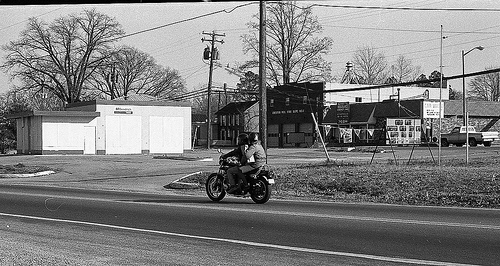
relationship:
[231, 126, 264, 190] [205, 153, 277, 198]
man riding motorcycle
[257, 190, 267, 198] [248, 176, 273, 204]
part belonging to wheel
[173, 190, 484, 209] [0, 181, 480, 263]
edge lining road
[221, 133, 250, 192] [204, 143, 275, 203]
man riding motorcycle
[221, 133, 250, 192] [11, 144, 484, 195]
man driving on road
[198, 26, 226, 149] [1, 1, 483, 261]
utility pole shown in picture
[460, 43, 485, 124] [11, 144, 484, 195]
street light standing near road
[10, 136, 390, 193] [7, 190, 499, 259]
parking lot near street